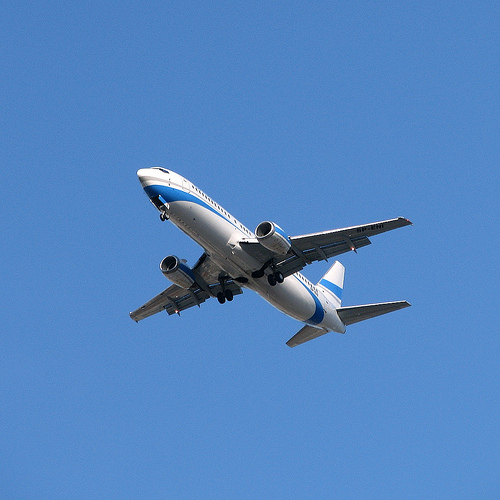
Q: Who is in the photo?
A: No one.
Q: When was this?
A: Daytime.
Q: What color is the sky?
A: Blue.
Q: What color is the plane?
A: White.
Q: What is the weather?
A: Sunny.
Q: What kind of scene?
A: Outdoor.